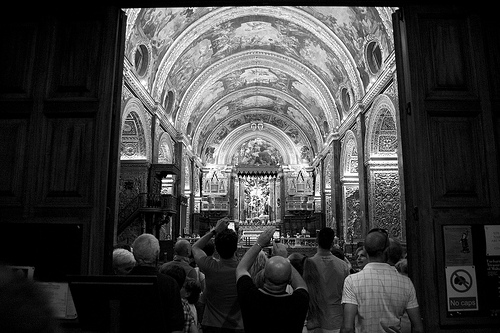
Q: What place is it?
A: It is a church.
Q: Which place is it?
A: It is a church.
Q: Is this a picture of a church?
A: Yes, it is showing a church.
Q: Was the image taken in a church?
A: Yes, it was taken in a church.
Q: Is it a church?
A: Yes, it is a church.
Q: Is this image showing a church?
A: Yes, it is showing a church.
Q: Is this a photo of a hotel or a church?
A: It is showing a church.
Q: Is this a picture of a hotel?
A: No, the picture is showing a church.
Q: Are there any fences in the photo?
A: No, there are no fences.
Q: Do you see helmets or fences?
A: No, there are no fences or helmets.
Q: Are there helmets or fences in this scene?
A: No, there are no fences or helmets.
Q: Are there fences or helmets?
A: No, there are no fences or helmets.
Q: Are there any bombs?
A: No, there are no bombs.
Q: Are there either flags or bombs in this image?
A: No, there are no bombs or flags.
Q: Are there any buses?
A: No, there are no buses.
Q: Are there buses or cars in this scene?
A: No, there are no buses or cars.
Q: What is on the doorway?
A: The sign is on the doorway.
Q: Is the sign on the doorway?
A: Yes, the sign is on the doorway.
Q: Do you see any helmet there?
A: No, there are no helmets.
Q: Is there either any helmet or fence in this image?
A: No, there are no helmets or fences.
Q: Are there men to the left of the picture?
A: Yes, there is a man to the left of the picture.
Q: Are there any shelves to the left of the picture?
A: No, there is a man to the left of the picture.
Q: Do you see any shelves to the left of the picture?
A: No, there is a man to the left of the picture.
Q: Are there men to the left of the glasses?
A: Yes, there is a man to the left of the glasses.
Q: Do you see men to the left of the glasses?
A: Yes, there is a man to the left of the glasses.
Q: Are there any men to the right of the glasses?
A: No, the man is to the left of the glasses.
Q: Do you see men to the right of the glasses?
A: No, the man is to the left of the glasses.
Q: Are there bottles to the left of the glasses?
A: No, there is a man to the left of the glasses.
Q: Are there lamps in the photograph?
A: No, there are no lamps.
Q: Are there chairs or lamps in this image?
A: No, there are no lamps or chairs.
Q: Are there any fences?
A: No, there are no fences.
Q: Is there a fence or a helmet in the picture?
A: No, there are no fences or helmets.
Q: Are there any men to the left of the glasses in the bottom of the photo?
A: Yes, there is a man to the left of the glasses.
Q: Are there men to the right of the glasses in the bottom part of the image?
A: No, the man is to the left of the glasses.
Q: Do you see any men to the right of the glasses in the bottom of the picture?
A: No, the man is to the left of the glasses.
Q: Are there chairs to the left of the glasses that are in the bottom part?
A: No, there is a man to the left of the glasses.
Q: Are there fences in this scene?
A: No, there are no fences.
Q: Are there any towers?
A: No, there are no towers.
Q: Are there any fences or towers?
A: No, there are no towers or fences.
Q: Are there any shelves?
A: No, there are no shelves.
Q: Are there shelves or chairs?
A: No, there are no shelves or chairs.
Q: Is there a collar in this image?
A: Yes, there is a collar.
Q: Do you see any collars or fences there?
A: Yes, there is a collar.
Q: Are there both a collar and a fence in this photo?
A: No, there is a collar but no fences.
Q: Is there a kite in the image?
A: No, there are no kites.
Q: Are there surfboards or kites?
A: No, there are no kites or surfboards.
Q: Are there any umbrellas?
A: No, there are no umbrellas.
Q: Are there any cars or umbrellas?
A: No, there are no umbrellas or cars.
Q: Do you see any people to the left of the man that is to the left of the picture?
A: Yes, there are people to the left of the man.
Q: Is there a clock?
A: No, there are no clocks.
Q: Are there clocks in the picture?
A: No, there are no clocks.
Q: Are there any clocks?
A: No, there are no clocks.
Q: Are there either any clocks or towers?
A: No, there are no clocks or towers.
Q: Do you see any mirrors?
A: No, there are no mirrors.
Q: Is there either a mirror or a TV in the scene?
A: No, there are no mirrors or televisions.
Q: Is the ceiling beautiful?
A: Yes, the ceiling is beautiful.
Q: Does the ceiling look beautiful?
A: Yes, the ceiling is beautiful.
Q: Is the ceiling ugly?
A: No, the ceiling is beautiful.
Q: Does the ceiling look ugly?
A: No, the ceiling is beautiful.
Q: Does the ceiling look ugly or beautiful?
A: The ceiling is beautiful.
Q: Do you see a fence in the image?
A: No, there are no fences.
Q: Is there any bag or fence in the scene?
A: No, there are no fences or bags.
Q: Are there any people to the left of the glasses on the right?
A: Yes, there are people to the left of the glasses.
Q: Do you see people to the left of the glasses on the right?
A: Yes, there are people to the left of the glasses.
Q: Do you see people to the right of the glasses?
A: No, the people are to the left of the glasses.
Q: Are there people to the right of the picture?
A: Yes, there are people to the right of the picture.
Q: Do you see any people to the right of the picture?
A: Yes, there are people to the right of the picture.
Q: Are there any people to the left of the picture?
A: No, the people are to the right of the picture.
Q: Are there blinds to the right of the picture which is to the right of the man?
A: No, there are people to the right of the picture.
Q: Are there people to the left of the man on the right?
A: Yes, there are people to the left of the man.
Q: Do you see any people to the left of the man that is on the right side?
A: Yes, there are people to the left of the man.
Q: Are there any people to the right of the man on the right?
A: No, the people are to the left of the man.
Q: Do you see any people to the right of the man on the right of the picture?
A: No, the people are to the left of the man.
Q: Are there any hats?
A: Yes, there is a hat.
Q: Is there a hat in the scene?
A: Yes, there is a hat.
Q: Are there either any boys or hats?
A: Yes, there is a hat.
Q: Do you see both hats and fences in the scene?
A: No, there is a hat but no fences.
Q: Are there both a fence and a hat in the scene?
A: No, there is a hat but no fences.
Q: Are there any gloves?
A: No, there are no gloves.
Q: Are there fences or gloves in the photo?
A: No, there are no gloves or fences.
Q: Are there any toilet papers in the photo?
A: No, there are no toilet papers.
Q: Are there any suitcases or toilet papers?
A: No, there are no toilet papers or suitcases.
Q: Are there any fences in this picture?
A: No, there are no fences.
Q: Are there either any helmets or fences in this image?
A: No, there are no fences or helmets.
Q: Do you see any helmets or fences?
A: No, there are no fences or helmets.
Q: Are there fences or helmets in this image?
A: No, there are no fences or helmets.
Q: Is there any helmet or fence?
A: No, there are no fences or helmets.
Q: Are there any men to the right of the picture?
A: Yes, there is a man to the right of the picture.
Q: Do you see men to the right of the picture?
A: Yes, there is a man to the right of the picture.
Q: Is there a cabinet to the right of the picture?
A: No, there is a man to the right of the picture.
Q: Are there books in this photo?
A: No, there are no books.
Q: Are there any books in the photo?
A: No, there are no books.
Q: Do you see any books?
A: No, there are no books.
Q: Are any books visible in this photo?
A: No, there are no books.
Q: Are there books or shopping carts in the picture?
A: No, there are no books or shopping carts.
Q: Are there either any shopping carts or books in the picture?
A: No, there are no books or shopping carts.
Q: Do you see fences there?
A: No, there are no fences.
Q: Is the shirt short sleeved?
A: Yes, the shirt is short sleeved.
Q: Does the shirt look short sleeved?
A: Yes, the shirt is short sleeved.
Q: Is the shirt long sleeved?
A: No, the shirt is short sleeved.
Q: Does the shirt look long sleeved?
A: No, the shirt is short sleeved.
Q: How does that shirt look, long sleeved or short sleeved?
A: The shirt is short sleeved.